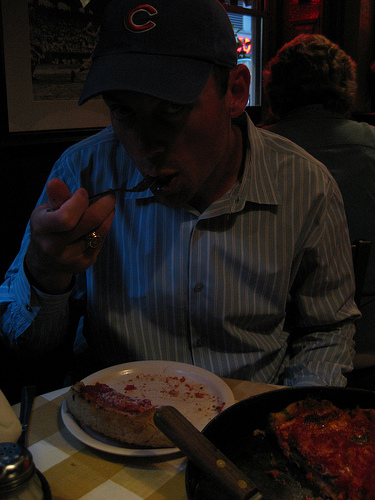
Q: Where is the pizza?
A: Black pan.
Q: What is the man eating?
A: Chicago pizza.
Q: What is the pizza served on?
A: A black platter.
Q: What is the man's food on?
A: A white plate.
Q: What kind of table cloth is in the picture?
A: Yellow white table cloth.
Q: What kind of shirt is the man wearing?
A: A blue and white striped shirt.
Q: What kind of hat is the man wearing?
A: A blue ball cap with a red c.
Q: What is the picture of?
A: A man eating.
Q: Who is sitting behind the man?
A: A woman.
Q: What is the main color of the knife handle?
A: Brown.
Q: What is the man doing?
A: Eating food.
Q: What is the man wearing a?
A: A ring.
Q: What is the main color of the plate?
A: White.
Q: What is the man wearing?
A: A cap.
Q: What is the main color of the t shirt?
A: Blue and white.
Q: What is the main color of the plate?
A: White.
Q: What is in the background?
A: There is a woman.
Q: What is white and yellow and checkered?
A: Tablecloth.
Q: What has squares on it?
A: Tablecloth.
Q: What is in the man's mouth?
A: Fork.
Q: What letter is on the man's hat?
A: C.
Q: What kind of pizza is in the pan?
A: Deep dish.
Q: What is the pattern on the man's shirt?
A: Stripes.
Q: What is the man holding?
A: Fork.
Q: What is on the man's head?
A: Cap.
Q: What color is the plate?
A: White.